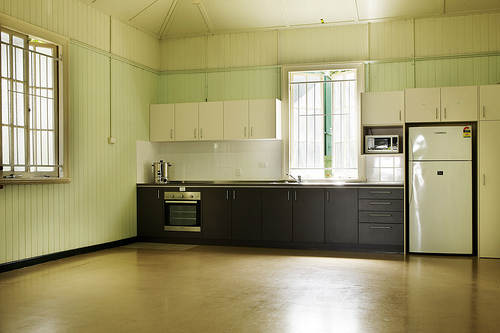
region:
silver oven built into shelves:
[162, 187, 202, 234]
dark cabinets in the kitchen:
[138, 183, 403, 251]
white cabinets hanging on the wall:
[150, 98, 283, 140]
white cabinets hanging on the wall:
[357, 82, 497, 124]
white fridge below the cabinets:
[407, 123, 473, 253]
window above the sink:
[286, 67, 356, 182]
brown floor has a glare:
[0, 240, 499, 332]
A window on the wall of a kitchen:
[279, 60, 370, 181]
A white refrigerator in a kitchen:
[406, 122, 481, 256]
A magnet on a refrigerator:
[459, 125, 472, 138]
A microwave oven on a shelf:
[361, 131, 407, 151]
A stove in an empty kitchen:
[158, 180, 208, 240]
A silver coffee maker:
[151, 157, 171, 182]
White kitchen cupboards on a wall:
[147, 97, 280, 139]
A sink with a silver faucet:
[276, 170, 338, 182]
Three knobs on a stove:
[164, 192, 199, 202]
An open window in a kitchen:
[3, 29, 60, 174]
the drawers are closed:
[357, 182, 404, 263]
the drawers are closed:
[347, 185, 393, 246]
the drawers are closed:
[358, 180, 405, 253]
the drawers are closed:
[353, 186, 407, 254]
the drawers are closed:
[355, 189, 402, 254]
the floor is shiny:
[102, 236, 328, 321]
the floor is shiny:
[106, 248, 336, 330]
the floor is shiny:
[100, 217, 365, 327]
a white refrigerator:
[405, 126, 473, 256]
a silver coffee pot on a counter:
[152, 160, 172, 186]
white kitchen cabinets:
[148, 98, 281, 143]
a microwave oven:
[365, 133, 399, 157]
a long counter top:
[157, 172, 402, 192]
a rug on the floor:
[104, 235, 199, 253]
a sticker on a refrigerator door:
[460, 123, 471, 138]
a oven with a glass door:
[161, 187, 207, 238]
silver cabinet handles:
[285, 189, 300, 201]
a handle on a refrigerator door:
[404, 160, 414, 201]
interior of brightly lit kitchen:
[0, 2, 497, 330]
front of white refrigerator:
[406, 124, 472, 254]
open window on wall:
[1, 28, 68, 182]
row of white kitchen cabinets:
[150, 98, 280, 141]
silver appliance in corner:
[150, 158, 170, 183]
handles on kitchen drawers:
[356, 187, 403, 247]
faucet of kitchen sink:
[282, 172, 303, 184]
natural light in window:
[290, 69, 357, 181]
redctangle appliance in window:
[364, 134, 400, 152]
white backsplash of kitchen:
[136, 142, 283, 182]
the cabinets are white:
[145, 86, 293, 153]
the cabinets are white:
[141, 95, 286, 151]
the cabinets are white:
[130, 88, 295, 160]